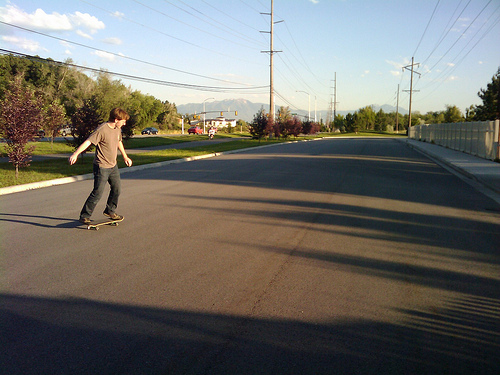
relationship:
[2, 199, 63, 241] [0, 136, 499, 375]
shadows cast on street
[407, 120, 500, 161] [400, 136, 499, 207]
fence along sidewalk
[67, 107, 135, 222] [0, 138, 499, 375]
man on street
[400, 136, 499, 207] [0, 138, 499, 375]
sidewalk along street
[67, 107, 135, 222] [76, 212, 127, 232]
man riding skateboard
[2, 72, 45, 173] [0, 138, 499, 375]
tree on side of street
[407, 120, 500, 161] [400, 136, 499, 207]
fence by sidewalk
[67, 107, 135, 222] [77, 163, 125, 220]
man wearing pants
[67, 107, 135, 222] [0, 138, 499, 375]
man skating on street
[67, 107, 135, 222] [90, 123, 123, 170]
man wearing shirt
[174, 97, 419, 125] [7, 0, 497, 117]
mountains are in background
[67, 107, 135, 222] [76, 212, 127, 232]
man on skateboard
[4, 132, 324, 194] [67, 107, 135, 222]
sidewalk behind man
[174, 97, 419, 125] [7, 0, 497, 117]
mountains are in distance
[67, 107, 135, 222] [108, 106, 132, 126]
man has hair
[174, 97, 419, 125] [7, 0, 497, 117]
mountains in distance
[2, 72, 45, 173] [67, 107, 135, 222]
tree behind man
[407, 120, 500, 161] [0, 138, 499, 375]
fence along street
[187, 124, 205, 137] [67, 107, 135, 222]
car behind man